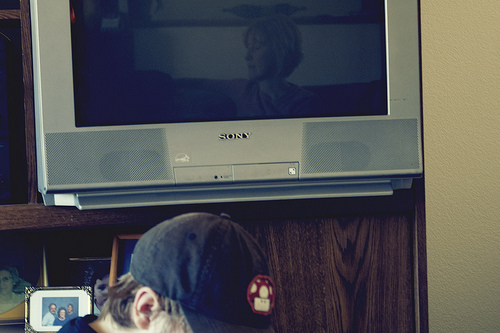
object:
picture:
[29, 279, 108, 328]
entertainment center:
[144, 204, 431, 324]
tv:
[31, 2, 418, 210]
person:
[61, 212, 271, 333]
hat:
[127, 212, 281, 326]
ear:
[121, 284, 164, 329]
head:
[238, 21, 301, 83]